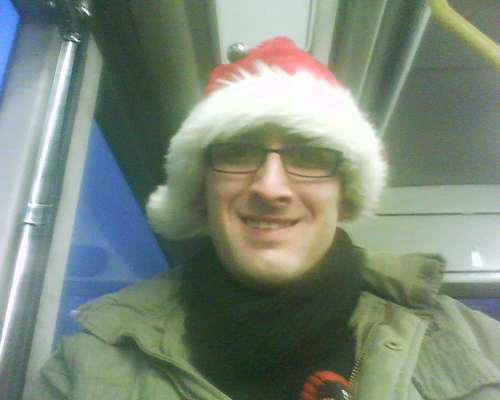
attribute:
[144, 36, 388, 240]
santa hat — red, white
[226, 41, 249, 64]
bell — silver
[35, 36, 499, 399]
man — smiling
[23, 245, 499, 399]
coat — green, khaki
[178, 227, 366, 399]
scarf — black, red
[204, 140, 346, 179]
glasses — black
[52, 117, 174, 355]
window — glass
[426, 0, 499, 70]
handle bar — yellow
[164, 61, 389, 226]
brim — white, fuzzy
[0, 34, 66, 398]
pipe — silver, metal